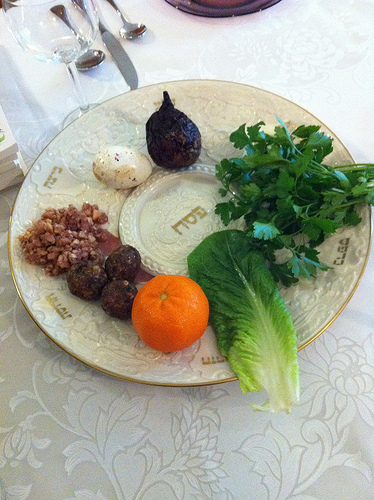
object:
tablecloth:
[0, 0, 374, 497]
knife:
[89, 0, 139, 92]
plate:
[10, 76, 372, 387]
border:
[7, 77, 372, 385]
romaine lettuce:
[187, 228, 301, 412]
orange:
[131, 274, 210, 355]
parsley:
[212, 114, 374, 288]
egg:
[92, 144, 152, 189]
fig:
[144, 90, 202, 170]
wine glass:
[1, 0, 100, 130]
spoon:
[50, 3, 105, 70]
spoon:
[106, 0, 147, 41]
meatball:
[105, 242, 141, 281]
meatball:
[102, 278, 138, 319]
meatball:
[69, 259, 107, 299]